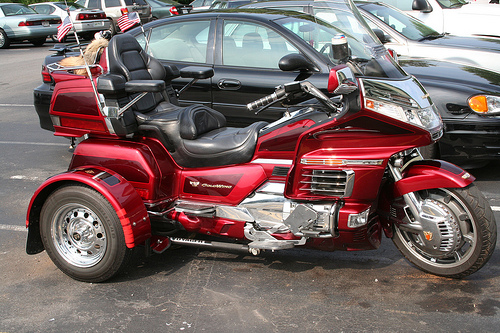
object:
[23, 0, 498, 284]
bike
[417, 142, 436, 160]
tire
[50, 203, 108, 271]
rim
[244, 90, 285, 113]
handle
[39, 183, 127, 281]
tire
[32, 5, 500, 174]
car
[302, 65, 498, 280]
front section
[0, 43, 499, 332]
street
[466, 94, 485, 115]
light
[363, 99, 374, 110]
light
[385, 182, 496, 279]
tire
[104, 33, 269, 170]
seat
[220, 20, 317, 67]
window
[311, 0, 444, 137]
guard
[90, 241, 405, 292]
shade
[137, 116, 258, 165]
edge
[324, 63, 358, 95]
mirror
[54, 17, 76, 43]
flag